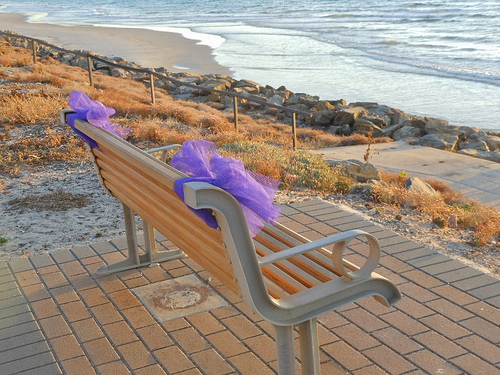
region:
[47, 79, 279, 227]
This is tulle on the bench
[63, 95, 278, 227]
The tulle is purple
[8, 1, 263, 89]
Ocean waves hitting the sand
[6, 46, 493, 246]
This is dry dune shrubbery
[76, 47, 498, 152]
Large pile of boulders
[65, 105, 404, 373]
This is a bench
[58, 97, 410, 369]
The bench is wooden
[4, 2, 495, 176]
This is at the beach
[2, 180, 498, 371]
The is a brick platform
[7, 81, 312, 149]
This is a wooden fence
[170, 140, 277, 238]
purple tulle ribbon around a bench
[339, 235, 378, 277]
circular metal arm decoration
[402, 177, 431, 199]
a large gray boulder in the grass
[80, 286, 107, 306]
a tan brick on the platform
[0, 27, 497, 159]
large rocks along the shoreline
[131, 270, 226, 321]
a square gray stone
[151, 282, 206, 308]
a red circular stain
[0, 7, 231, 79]
brown sand on the beach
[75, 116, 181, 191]
a long wooden slat on the top of a bench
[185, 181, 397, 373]
curved metal on the side of a bench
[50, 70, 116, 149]
purple bow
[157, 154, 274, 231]
purple bow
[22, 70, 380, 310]
wooden bench with purple bow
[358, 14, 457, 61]
waves in white and gray ocean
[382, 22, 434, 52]
waves in white and gray ocean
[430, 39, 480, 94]
waves in white and gray ocean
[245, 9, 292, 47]
waves in white and gray ocean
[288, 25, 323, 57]
waves in white and gray ocean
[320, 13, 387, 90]
waves in white and gray ocean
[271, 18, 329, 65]
waves in white and gray ocean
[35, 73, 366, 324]
wooden bench with purple bows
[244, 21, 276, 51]
waves in white and gray ocean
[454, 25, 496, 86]
waves in white and gray ocean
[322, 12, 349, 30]
waves in white and gray ocean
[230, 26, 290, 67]
waves in white and gray ocean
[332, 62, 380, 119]
waves in white and gray ocean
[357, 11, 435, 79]
waves in white and gray ocean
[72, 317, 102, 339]
single brick on ground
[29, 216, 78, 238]
mix of sand and rocks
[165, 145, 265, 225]
purple ruffle on corner of bench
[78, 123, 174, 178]
wooden plank making bench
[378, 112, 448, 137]
large rocks along the shore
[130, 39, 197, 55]
beach sand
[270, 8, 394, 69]
incoming waves from ocean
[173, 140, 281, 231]
a purple bow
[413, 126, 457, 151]
a large gray rock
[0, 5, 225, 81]
a small beach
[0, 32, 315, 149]
a long rail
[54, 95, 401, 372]
a beige outdoor bench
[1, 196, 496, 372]
a bricke tiled outdoor patio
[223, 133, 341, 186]
green and brown grass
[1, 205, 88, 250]
a small area of gray sand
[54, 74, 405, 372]
wood and metal bench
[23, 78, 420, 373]
wood metal bench on bricks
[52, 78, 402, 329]
wood and metal bench with purple bows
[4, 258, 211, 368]
Pad made of bricks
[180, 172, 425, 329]
metal arm of bench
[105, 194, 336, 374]
metal legs supporting bench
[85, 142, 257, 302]
wooden back of bench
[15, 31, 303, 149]
wood post fence along hillside